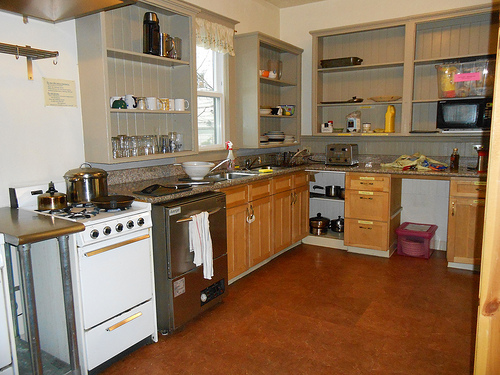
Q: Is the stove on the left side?
A: Yes, the stove is on the left of the image.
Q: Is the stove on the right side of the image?
A: No, the stove is on the left of the image.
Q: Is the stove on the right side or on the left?
A: The stove is on the left of the image.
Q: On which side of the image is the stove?
A: The stove is on the left of the image.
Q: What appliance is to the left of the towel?
A: The appliance is a stove.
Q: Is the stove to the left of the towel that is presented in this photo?
A: Yes, the stove is to the left of the towel.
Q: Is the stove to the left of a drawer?
A: No, the stove is to the left of the towel.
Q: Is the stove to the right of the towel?
A: No, the stove is to the left of the towel.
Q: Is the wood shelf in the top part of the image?
A: Yes, the shelf is in the top of the image.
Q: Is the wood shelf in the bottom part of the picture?
A: No, the shelf is in the top of the image.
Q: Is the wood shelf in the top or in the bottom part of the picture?
A: The shelf is in the top of the image.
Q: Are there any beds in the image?
A: No, there are no beds.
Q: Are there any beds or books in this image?
A: No, there are no beds or books.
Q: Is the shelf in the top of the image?
A: Yes, the shelf is in the top of the image.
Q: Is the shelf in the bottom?
A: No, the shelf is in the top of the image.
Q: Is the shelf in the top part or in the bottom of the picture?
A: The shelf is in the top of the image.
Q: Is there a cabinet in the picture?
A: Yes, there is a cabinet.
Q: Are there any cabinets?
A: Yes, there is a cabinet.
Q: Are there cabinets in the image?
A: Yes, there is a cabinet.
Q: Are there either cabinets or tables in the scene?
A: Yes, there is a cabinet.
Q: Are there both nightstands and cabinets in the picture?
A: No, there is a cabinet but no nightstands.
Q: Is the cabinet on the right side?
A: Yes, the cabinet is on the right of the image.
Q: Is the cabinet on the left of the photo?
A: No, the cabinet is on the right of the image.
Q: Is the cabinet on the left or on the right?
A: The cabinet is on the right of the image.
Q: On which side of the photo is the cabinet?
A: The cabinet is on the right of the image.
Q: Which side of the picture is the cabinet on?
A: The cabinet is on the right of the image.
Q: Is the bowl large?
A: Yes, the bowl is large.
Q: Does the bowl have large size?
A: Yes, the bowl is large.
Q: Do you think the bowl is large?
A: Yes, the bowl is large.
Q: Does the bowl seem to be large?
A: Yes, the bowl is large.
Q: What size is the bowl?
A: The bowl is large.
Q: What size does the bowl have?
A: The bowl has large size.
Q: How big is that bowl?
A: The bowl is large.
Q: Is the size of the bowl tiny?
A: No, the bowl is large.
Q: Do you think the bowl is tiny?
A: No, the bowl is large.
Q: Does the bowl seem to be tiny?
A: No, the bowl is large.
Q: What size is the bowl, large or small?
A: The bowl is large.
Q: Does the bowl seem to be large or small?
A: The bowl is large.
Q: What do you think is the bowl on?
A: The bowl is on the counter.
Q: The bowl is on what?
A: The bowl is on the counter.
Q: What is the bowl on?
A: The bowl is on the counter.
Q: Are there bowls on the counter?
A: Yes, there is a bowl on the counter.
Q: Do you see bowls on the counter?
A: Yes, there is a bowl on the counter.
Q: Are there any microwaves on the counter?
A: No, there is a bowl on the counter.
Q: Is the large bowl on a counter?
A: Yes, the bowl is on a counter.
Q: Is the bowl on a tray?
A: No, the bowl is on a counter.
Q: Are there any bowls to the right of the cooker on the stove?
A: Yes, there is a bowl to the right of the cooker.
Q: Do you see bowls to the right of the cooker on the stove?
A: Yes, there is a bowl to the right of the cooker.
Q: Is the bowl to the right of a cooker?
A: Yes, the bowl is to the right of a cooker.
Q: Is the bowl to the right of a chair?
A: No, the bowl is to the right of a cooker.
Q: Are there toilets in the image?
A: No, there are no toilets.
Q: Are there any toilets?
A: No, there are no toilets.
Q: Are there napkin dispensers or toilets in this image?
A: No, there are no toilets or napkin dispensers.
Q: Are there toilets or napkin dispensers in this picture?
A: No, there are no toilets or napkin dispensers.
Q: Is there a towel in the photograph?
A: Yes, there is a towel.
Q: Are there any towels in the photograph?
A: Yes, there is a towel.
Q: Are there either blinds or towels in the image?
A: Yes, there is a towel.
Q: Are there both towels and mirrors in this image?
A: No, there is a towel but no mirrors.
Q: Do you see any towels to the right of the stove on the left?
A: Yes, there is a towel to the right of the stove.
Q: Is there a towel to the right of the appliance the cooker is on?
A: Yes, there is a towel to the right of the stove.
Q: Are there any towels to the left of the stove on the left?
A: No, the towel is to the right of the stove.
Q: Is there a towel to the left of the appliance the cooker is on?
A: No, the towel is to the right of the stove.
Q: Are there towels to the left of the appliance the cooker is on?
A: No, the towel is to the right of the stove.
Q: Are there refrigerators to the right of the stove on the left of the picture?
A: No, there is a towel to the right of the stove.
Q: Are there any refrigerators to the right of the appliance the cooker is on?
A: No, there is a towel to the right of the stove.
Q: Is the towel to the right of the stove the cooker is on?
A: Yes, the towel is to the right of the stove.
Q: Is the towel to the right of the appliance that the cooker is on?
A: Yes, the towel is to the right of the stove.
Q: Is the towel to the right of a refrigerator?
A: No, the towel is to the right of the stove.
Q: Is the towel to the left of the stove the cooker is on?
A: No, the towel is to the right of the stove.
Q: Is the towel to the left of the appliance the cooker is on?
A: No, the towel is to the right of the stove.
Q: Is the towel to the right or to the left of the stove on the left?
A: The towel is to the right of the stove.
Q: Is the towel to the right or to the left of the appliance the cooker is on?
A: The towel is to the right of the stove.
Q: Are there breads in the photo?
A: No, there are no breads.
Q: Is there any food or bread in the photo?
A: No, there are no breads or food.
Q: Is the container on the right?
A: Yes, the container is on the right of the image.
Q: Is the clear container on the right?
A: Yes, the container is on the right of the image.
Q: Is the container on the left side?
A: No, the container is on the right of the image.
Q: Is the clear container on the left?
A: No, the container is on the right of the image.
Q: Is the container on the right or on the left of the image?
A: The container is on the right of the image.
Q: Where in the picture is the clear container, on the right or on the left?
A: The container is on the right of the image.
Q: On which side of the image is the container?
A: The container is on the right of the image.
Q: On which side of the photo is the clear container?
A: The container is on the right of the image.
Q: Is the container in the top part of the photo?
A: Yes, the container is in the top of the image.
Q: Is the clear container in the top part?
A: Yes, the container is in the top of the image.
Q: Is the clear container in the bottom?
A: No, the container is in the top of the image.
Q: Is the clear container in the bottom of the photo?
A: No, the container is in the top of the image.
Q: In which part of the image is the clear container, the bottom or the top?
A: The container is in the top of the image.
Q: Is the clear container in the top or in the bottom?
A: The container is in the top of the image.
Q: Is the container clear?
A: Yes, the container is clear.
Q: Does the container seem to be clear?
A: Yes, the container is clear.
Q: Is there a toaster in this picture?
A: Yes, there is a toaster.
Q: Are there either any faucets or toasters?
A: Yes, there is a toaster.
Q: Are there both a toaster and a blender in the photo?
A: No, there is a toaster but no blenders.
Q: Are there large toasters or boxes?
A: Yes, there is a large toaster.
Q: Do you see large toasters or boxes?
A: Yes, there is a large toaster.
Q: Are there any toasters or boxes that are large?
A: Yes, the toaster is large.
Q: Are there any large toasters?
A: Yes, there is a large toaster.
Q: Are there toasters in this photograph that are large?
A: Yes, there is a large toaster.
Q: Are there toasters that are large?
A: Yes, there is a toaster that is large.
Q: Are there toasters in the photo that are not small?
A: Yes, there is a large toaster.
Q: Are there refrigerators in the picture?
A: No, there are no refrigerators.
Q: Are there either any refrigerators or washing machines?
A: No, there are no refrigerators or washing machines.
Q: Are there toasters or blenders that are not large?
A: No, there is a toaster but it is large.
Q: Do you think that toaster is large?
A: Yes, the toaster is large.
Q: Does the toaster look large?
A: Yes, the toaster is large.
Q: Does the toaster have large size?
A: Yes, the toaster is large.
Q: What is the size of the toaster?
A: The toaster is large.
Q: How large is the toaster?
A: The toaster is large.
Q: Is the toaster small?
A: No, the toaster is large.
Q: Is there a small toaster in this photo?
A: No, there is a toaster but it is large.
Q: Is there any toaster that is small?
A: No, there is a toaster but it is large.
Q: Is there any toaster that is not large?
A: No, there is a toaster but it is large.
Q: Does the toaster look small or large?
A: The toaster is large.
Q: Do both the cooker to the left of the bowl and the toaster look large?
A: Yes, both the cooker and the toaster are large.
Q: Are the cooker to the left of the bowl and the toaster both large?
A: Yes, both the cooker and the toaster are large.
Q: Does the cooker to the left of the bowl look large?
A: Yes, the cooker is large.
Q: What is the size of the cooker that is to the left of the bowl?
A: The cooker is large.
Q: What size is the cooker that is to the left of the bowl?
A: The cooker is large.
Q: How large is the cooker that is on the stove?
A: The cooker is large.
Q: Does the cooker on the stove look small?
A: No, the cooker is large.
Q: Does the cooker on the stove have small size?
A: No, the cooker is large.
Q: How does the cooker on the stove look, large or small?
A: The cooker is large.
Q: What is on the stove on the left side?
A: The cooker is on the stove.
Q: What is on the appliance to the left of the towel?
A: The cooker is on the stove.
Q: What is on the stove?
A: The cooker is on the stove.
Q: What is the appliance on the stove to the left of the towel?
A: The appliance is a cooker.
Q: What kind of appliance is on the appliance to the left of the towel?
A: The appliance is a cooker.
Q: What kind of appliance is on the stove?
A: The appliance is a cooker.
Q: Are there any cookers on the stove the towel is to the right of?
A: Yes, there is a cooker on the stove.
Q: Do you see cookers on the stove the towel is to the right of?
A: Yes, there is a cooker on the stove.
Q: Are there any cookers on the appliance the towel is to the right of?
A: Yes, there is a cooker on the stove.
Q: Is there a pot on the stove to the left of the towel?
A: No, there is a cooker on the stove.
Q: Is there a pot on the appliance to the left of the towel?
A: No, there is a cooker on the stove.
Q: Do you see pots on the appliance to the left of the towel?
A: No, there is a cooker on the stove.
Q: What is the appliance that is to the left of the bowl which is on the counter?
A: The appliance is a cooker.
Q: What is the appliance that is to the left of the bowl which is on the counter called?
A: The appliance is a cooker.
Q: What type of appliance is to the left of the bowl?
A: The appliance is a cooker.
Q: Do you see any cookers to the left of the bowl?
A: Yes, there is a cooker to the left of the bowl.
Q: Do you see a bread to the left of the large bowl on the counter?
A: No, there is a cooker to the left of the bowl.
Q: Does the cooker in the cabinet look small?
A: Yes, the cooker is small.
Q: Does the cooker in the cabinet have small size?
A: Yes, the cooker is small.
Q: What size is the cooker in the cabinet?
A: The cooker is small.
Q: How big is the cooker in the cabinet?
A: The cooker is small.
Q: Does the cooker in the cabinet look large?
A: No, the cooker is small.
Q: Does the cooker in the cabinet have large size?
A: No, the cooker is small.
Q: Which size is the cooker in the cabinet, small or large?
A: The cooker is small.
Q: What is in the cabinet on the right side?
A: The cooker is in the cabinet.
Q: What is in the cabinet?
A: The cooker is in the cabinet.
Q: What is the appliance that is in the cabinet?
A: The appliance is a cooker.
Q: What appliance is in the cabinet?
A: The appliance is a cooker.